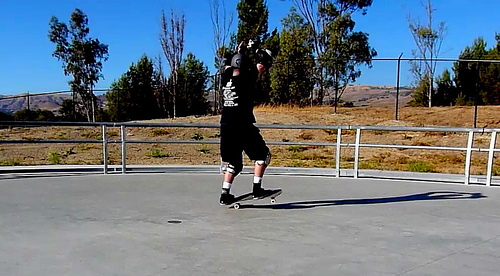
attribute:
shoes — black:
[220, 182, 267, 204]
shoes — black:
[219, 185, 275, 202]